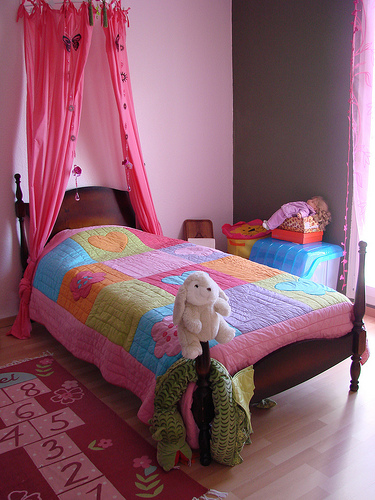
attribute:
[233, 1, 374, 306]
pink wall — light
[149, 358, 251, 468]
dragon — green, stuffed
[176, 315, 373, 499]
floorboards — wooden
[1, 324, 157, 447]
floorboards — wooden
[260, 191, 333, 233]
toy doll — pink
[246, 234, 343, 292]
container — plastic, blue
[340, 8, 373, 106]
pink drapes — hot pink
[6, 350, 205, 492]
rug — pattern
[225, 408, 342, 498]
floorboards — wooden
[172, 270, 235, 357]
stuffed bunny — white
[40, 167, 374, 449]
bed — dark, brown, wooden